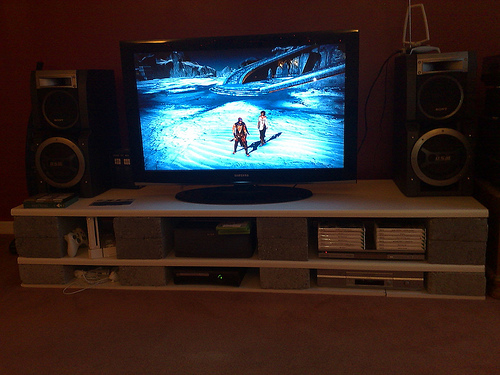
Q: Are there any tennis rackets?
A: No, there are no tennis rackets.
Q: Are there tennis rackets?
A: No, there are no tennis rackets.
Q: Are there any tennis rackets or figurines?
A: No, there are no tennis rackets or figurines.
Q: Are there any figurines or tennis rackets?
A: No, there are no tennis rackets or figurines.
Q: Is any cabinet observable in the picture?
A: Yes, there is a cabinet.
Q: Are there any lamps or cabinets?
A: Yes, there is a cabinet.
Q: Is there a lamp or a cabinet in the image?
A: Yes, there is a cabinet.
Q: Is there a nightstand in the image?
A: No, there are no nightstands.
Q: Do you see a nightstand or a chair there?
A: No, there are no nightstands or chairs.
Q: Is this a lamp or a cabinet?
A: This is a cabinet.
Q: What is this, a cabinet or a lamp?
A: This is a cabinet.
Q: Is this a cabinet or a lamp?
A: This is a cabinet.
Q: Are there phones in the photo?
A: No, there are no phones.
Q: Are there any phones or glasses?
A: No, there are no phones or glasses.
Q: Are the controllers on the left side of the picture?
A: Yes, the controllers are on the left of the image.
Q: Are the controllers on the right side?
A: No, the controllers are on the left of the image.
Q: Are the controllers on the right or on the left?
A: The controllers are on the left of the image.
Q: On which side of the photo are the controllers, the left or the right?
A: The controllers are on the left of the image.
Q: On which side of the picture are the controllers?
A: The controllers are on the left of the image.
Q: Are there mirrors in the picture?
A: No, there are no mirrors.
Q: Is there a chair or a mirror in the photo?
A: No, there are no mirrors or chairs.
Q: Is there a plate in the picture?
A: No, there are no plates.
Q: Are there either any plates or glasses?
A: No, there are no plates or glasses.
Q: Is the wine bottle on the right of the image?
A: Yes, the wine bottle is on the right of the image.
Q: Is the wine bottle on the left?
A: No, the wine bottle is on the right of the image.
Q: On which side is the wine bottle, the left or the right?
A: The wine bottle is on the right of the image.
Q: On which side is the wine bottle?
A: The wine bottle is on the right of the image.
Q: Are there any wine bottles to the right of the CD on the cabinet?
A: Yes, there is a wine bottle to the right of the CD.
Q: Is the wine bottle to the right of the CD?
A: Yes, the wine bottle is to the right of the CD.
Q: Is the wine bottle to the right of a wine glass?
A: No, the wine bottle is to the right of the CD.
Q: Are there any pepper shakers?
A: No, there are no pepper shakers.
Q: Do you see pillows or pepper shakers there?
A: No, there are no pepper shakers or pillows.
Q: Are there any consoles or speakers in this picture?
A: Yes, there is a speaker.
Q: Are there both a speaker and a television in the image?
A: Yes, there are both a speaker and a television.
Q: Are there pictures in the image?
A: No, there are no pictures.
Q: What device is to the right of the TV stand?
A: The device is a speaker.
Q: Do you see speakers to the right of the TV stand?
A: Yes, there is a speaker to the right of the TV stand.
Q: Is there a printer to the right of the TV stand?
A: No, there is a speaker to the right of the TV stand.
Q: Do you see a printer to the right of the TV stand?
A: No, there is a speaker to the right of the TV stand.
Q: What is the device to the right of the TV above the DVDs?
A: The device is a speaker.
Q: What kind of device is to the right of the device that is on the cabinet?
A: The device is a speaker.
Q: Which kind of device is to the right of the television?
A: The device is a speaker.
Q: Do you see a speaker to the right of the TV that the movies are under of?
A: Yes, there is a speaker to the right of the television.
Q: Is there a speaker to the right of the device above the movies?
A: Yes, there is a speaker to the right of the television.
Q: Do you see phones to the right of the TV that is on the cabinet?
A: No, there is a speaker to the right of the television.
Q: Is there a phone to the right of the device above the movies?
A: No, there is a speaker to the right of the television.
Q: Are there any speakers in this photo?
A: Yes, there is a speaker.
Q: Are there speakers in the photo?
A: Yes, there is a speaker.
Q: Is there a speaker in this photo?
A: Yes, there is a speaker.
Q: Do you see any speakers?
A: Yes, there is a speaker.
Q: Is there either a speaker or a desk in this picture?
A: Yes, there is a speaker.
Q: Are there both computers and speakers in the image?
A: No, there is a speaker but no computers.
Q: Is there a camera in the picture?
A: No, there are no cameras.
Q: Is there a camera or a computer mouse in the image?
A: No, there are no cameras or computer mice.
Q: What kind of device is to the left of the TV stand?
A: The device is a speaker.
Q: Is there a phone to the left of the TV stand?
A: No, there is a speaker to the left of the TV stand.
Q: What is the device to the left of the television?
A: The device is a speaker.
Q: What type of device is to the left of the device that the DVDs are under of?
A: The device is a speaker.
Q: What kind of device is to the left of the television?
A: The device is a speaker.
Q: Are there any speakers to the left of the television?
A: Yes, there is a speaker to the left of the television.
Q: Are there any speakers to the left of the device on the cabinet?
A: Yes, there is a speaker to the left of the television.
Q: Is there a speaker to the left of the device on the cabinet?
A: Yes, there is a speaker to the left of the television.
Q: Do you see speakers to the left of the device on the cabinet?
A: Yes, there is a speaker to the left of the television.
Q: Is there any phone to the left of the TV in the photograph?
A: No, there is a speaker to the left of the TV.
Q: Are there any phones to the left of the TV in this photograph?
A: No, there is a speaker to the left of the TV.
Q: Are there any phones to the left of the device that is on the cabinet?
A: No, there is a speaker to the left of the TV.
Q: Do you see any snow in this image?
A: Yes, there is snow.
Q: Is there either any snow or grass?
A: Yes, there is snow.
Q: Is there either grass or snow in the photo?
A: Yes, there is snow.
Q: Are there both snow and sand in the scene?
A: No, there is snow but no sand.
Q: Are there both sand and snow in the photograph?
A: No, there is snow but no sand.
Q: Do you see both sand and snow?
A: No, there is snow but no sand.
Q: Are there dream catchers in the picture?
A: No, there are no dream catchers.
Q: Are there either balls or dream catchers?
A: No, there are no dream catchers or balls.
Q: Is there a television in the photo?
A: Yes, there is a television.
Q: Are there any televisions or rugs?
A: Yes, there is a television.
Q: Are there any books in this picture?
A: No, there are no books.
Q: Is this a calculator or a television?
A: This is a television.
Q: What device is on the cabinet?
A: The device is a television.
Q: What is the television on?
A: The television is on the cabinet.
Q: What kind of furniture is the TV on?
A: The TV is on the cabinet.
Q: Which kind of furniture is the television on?
A: The TV is on the cabinet.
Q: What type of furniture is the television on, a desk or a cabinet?
A: The television is on a cabinet.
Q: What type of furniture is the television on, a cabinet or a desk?
A: The television is on a cabinet.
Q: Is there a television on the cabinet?
A: Yes, there is a television on the cabinet.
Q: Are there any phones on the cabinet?
A: No, there is a television on the cabinet.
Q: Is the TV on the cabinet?
A: Yes, the TV is on the cabinet.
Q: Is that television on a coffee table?
A: No, the television is on the cabinet.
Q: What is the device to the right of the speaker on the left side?
A: The device is a television.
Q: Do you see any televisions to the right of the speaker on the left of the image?
A: Yes, there is a television to the right of the speaker.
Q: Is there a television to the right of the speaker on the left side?
A: Yes, there is a television to the right of the speaker.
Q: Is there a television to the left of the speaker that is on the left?
A: No, the television is to the right of the speaker.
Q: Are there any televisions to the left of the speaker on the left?
A: No, the television is to the right of the speaker.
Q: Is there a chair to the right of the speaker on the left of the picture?
A: No, there is a television to the right of the speaker.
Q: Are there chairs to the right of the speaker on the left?
A: No, there is a television to the right of the speaker.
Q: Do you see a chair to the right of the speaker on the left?
A: No, there is a television to the right of the speaker.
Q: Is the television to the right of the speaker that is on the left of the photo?
A: Yes, the television is to the right of the speaker.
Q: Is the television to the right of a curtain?
A: No, the television is to the right of the speaker.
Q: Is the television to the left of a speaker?
A: No, the television is to the right of a speaker.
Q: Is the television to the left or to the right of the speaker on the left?
A: The television is to the right of the speaker.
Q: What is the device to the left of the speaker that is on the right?
A: The device is a television.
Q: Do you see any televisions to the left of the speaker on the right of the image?
A: Yes, there is a television to the left of the speaker.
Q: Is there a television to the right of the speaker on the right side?
A: No, the television is to the left of the speaker.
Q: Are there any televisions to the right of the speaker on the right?
A: No, the television is to the left of the speaker.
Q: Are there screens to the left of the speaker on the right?
A: No, there is a television to the left of the speaker.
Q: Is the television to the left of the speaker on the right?
A: Yes, the television is to the left of the speaker.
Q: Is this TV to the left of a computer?
A: No, the TV is to the left of the speaker.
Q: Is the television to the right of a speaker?
A: No, the television is to the left of a speaker.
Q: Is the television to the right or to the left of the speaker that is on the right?
A: The television is to the left of the speaker.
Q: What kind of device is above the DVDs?
A: The device is a television.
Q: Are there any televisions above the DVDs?
A: Yes, there is a television above the DVDs.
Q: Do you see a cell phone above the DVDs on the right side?
A: No, there is a television above the DVDs.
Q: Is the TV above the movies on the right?
A: Yes, the TV is above the DVDs.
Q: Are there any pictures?
A: No, there are no pictures.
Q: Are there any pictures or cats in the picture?
A: No, there are no pictures or cats.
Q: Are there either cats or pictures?
A: No, there are no pictures or cats.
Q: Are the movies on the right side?
A: Yes, the movies are on the right of the image.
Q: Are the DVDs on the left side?
A: No, the DVDs are on the right of the image.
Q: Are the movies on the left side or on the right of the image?
A: The movies are on the right of the image.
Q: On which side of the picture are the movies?
A: The movies are on the right of the image.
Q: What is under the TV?
A: The movies are under the TV.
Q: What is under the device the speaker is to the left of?
A: The movies are under the TV.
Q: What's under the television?
A: The movies are under the TV.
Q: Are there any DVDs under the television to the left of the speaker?
A: Yes, there are DVDs under the television.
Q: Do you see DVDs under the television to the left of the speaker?
A: Yes, there are DVDs under the television.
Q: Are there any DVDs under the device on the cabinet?
A: Yes, there are DVDs under the television.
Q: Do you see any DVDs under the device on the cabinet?
A: Yes, there are DVDs under the television.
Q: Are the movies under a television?
A: Yes, the movies are under a television.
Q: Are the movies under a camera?
A: No, the movies are under a television.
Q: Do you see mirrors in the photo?
A: No, there are no mirrors.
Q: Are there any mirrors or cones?
A: No, there are no mirrors or cones.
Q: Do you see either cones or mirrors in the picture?
A: No, there are no mirrors or cones.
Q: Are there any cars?
A: No, there are no cars.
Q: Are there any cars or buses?
A: No, there are no cars or buses.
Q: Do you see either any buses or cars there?
A: No, there are no cars or buses.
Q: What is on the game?
A: The characters are on the game.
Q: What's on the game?
A: The characters are on the game.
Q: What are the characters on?
A: The characters are on the game.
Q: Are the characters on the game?
A: Yes, the characters are on the game.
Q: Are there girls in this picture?
A: No, there are no girls.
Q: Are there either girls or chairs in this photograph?
A: No, there are no girls or chairs.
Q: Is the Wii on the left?
A: Yes, the Wii is on the left of the image.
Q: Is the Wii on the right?
A: No, the Wii is on the left of the image.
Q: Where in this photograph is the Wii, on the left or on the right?
A: The Wii is on the left of the image.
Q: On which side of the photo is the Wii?
A: The Wii is on the left of the image.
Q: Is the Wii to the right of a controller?
A: Yes, the Wii is to the right of a controller.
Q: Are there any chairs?
A: No, there are no chairs.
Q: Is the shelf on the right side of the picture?
A: Yes, the shelf is on the right of the image.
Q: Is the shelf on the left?
A: No, the shelf is on the right of the image.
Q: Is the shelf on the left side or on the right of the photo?
A: The shelf is on the right of the image.